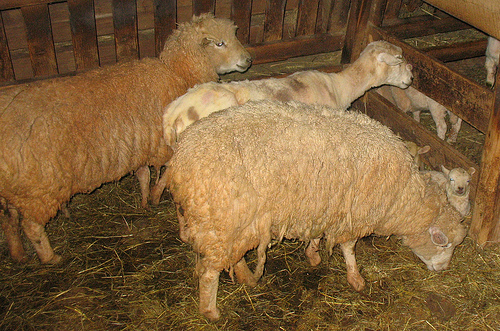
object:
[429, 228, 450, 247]
sheep's ear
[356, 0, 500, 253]
section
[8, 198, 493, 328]
hay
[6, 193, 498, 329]
ground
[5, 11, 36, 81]
pen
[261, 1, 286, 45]
slat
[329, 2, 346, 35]
slat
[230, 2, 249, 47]
slat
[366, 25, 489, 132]
slat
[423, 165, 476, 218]
sheep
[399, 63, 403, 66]
eyes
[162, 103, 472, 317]
sheep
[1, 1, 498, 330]
background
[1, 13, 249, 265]
sheep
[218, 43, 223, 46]
eye ball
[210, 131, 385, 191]
wool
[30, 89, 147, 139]
wool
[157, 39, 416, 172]
lamb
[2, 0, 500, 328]
barn